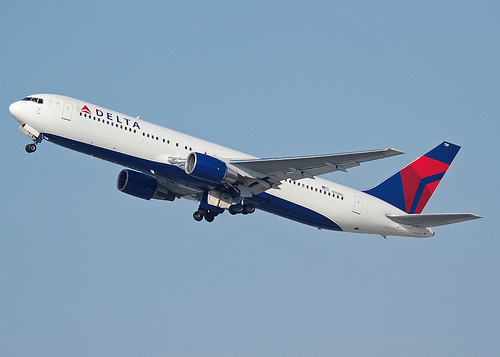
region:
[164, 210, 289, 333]
the sky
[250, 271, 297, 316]
the sky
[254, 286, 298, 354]
the sky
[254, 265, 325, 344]
the sky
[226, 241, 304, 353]
the sky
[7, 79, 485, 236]
the plane in the sky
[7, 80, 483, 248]
the plane in mid air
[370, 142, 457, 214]
the red and blue tail of the plane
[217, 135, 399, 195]
the wing of the plane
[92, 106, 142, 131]
the word on the side of the plane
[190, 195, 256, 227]
the back wheels under the plane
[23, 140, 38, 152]
the front wheels under the plane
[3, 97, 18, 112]
the nose of the plane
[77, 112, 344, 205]
the windows on the side of the plane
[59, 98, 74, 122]
the door on the side of the plane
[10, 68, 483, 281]
plane flying at an angle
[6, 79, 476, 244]
the plane body is white in color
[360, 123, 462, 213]
the plane tail is blue and red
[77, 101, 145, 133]
graphic logo on side of plane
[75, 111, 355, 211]
row of windows across plane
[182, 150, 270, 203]
engine below plane wing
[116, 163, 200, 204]
engine below plane wing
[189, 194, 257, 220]
plane tires are in down position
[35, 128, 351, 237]
black marking underneath plane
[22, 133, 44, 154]
front wheel of plane is down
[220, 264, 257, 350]
the sky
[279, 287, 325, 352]
the sky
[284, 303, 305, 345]
the sky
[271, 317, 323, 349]
the sky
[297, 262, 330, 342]
the sky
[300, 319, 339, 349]
the sky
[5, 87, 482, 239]
THE BODY OF THE PLANE IS WHITE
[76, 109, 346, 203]
THE PLANE HAS MANY WINDOWS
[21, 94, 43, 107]
THE PLANE'S WINDSHIELD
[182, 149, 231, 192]
THE PLANE HAS BLUE ENGINE IS BLUE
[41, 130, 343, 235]
THE UNDERBELLY OF THE PLANE IS BLUE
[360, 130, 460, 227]
THE PLANE'S TAIL IS RED AND BLUE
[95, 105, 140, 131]
DELTA IS PAINTED ON THE SIDE OF THE PLANE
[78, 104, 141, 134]
THE WORD DELTA IS BLUE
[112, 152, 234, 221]
THE PLANE HAS TWO ENGINES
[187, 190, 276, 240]
THE LANDING GEAR IS DOWN